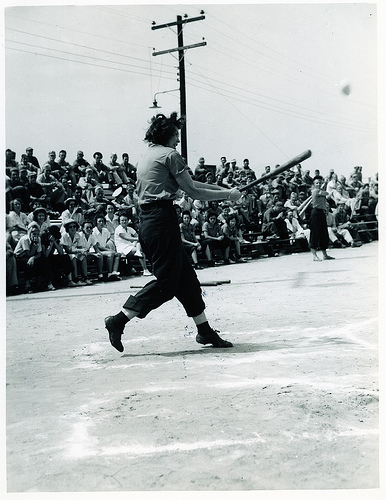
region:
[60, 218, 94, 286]
person sitting next to person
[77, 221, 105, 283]
person sitting next to person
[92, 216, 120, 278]
person sitting next to person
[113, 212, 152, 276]
person sitting next to person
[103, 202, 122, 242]
person sitting next to person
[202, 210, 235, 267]
person sitting next to person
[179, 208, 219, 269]
person sitting next to person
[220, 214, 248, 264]
person sitting next to person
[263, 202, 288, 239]
person sitting next to person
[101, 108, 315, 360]
a lady softball player from long ago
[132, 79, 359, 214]
lady batter has just walloped the ball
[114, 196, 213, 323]
lady batter wears men's slacks with cuffs turned up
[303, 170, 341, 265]
a lady 3rd base coach wearing a long skirt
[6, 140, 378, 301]
plenty of spectators for this exotic sport of ladies' ball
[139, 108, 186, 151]
lady batter is not wearing any head covering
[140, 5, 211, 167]
telephone pole in the background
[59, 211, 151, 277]
lots of ladies watching the lady at bat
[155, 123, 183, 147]
Person has dark hair.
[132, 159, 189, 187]
Person wearing short sleeve shirt.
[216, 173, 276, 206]
Person holding baseball bat.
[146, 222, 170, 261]
Person wearing black pants.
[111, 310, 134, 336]
Person wearing black socks.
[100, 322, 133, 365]
Person wearing black shoes.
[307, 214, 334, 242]
Person wearing black pants.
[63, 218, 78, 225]
Person wearing hat on head.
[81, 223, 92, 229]
Sunglasses on person's face.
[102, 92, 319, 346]
woman swinging at baseball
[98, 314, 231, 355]
black shoes worn by the player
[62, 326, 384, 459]
white chalk lines on the field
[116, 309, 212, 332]
black socks of the batter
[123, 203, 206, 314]
black pants worn by the batter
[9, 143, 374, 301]
crowd watching the baseball game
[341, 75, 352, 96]
ball being swung at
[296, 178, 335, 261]
woman in the warm up circle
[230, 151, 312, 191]
bat held by batter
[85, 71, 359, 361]
a woman hitting a softball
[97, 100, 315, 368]
a woman playing softball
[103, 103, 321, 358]
a woman holding a bat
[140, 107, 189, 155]
the head of a woman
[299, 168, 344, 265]
a woman holding two bats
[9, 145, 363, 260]
spectators at a softball game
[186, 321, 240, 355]
the foot of a woman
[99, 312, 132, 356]
the foot of a woman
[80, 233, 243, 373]
the legs of a woman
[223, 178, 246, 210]
two hands holding a bat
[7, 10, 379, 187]
The hazy sky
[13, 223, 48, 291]
a person is sitting down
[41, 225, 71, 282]
a person is sitting down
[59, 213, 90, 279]
a person is sitting down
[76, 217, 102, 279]
a person is sitting down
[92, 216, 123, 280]
a person is sitting down